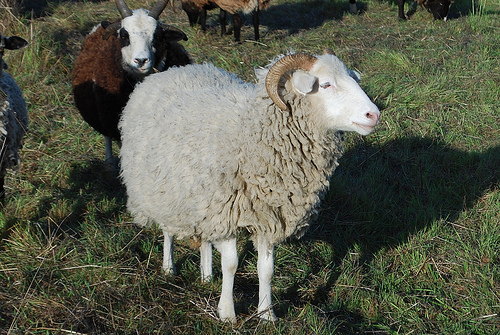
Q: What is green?
A: Grass.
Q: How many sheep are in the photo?
A: Two.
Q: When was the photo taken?
A: Daytime.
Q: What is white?
A: One sheep.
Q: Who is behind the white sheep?
A: Brown sheep.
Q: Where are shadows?
A: On the grass.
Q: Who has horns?
A: Sheep.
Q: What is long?
A: The grass.